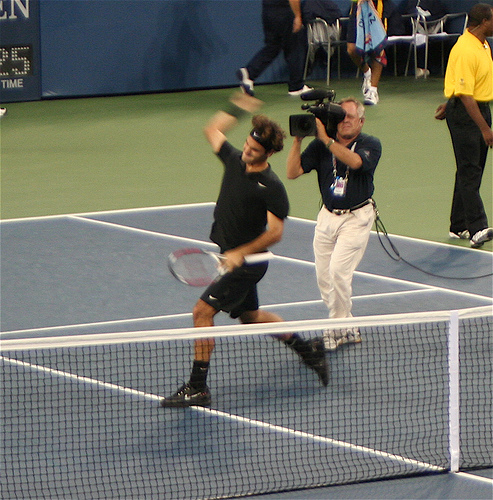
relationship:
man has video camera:
[286, 97, 380, 351] [290, 89, 344, 138]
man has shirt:
[434, 3, 491, 244] [445, 28, 492, 99]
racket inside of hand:
[167, 251, 277, 285] [219, 253, 245, 272]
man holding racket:
[158, 92, 328, 408] [167, 251, 277, 285]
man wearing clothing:
[158, 92, 328, 408] [202, 141, 290, 317]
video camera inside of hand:
[290, 89, 344, 138] [314, 117, 326, 140]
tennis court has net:
[2, 200, 491, 499] [0, 305, 490, 499]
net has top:
[0, 305, 490, 499] [0, 304, 492, 350]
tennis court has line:
[2, 200, 491, 499] [69, 217, 429, 290]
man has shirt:
[158, 92, 328, 408] [209, 142, 287, 247]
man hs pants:
[286, 97, 380, 351] [312, 198, 377, 329]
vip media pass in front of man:
[331, 176, 347, 197] [286, 97, 380, 351]